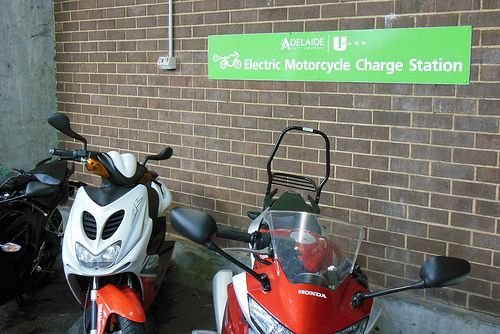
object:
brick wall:
[53, 0, 499, 317]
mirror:
[47, 112, 73, 136]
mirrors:
[416, 254, 472, 288]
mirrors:
[170, 207, 218, 246]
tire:
[106, 315, 148, 333]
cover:
[96, 282, 149, 333]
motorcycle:
[0, 147, 76, 334]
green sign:
[206, 25, 472, 85]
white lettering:
[243, 58, 249, 70]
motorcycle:
[170, 124, 470, 334]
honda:
[297, 288, 325, 297]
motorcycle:
[47, 112, 178, 333]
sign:
[207, 25, 473, 85]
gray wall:
[0, 0, 59, 170]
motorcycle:
[211, 51, 244, 70]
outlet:
[157, 57, 178, 71]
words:
[243, 58, 283, 70]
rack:
[266, 125, 330, 200]